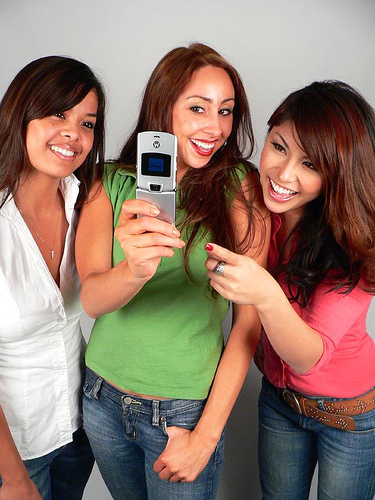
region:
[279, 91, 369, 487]
woman wearing blue jeans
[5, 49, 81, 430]
woman wearing white shirt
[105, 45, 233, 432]
woman holding a phone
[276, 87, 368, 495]
woman wearing brown belt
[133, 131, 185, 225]
silver motorola cell phone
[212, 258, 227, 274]
silver rings on her finger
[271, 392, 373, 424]
brown belt with a silver buckle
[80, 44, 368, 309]
two girls taking a selfie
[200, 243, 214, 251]
red fingernail polish on a fingernail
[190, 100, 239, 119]
brown eyes looking into phone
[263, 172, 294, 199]
pearly white teeth in mouth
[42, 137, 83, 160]
white teeth with red lipstick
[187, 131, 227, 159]
white teeth with red lipstick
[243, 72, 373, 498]
this is a lady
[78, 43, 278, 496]
this is a lady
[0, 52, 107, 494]
this is a lady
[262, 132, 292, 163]
an eye of a person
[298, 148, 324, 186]
an eye of a person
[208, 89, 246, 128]
an eye of a person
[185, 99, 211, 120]
an eye of a person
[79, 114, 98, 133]
an eye of a person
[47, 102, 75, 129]
an eye of a person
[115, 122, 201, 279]
this is a phone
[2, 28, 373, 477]
Three young females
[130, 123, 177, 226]
Outdated flip phone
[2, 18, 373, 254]
Three smiling girls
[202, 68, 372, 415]
A female in pink shirt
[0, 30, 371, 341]
Three best friends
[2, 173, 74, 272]
Beautiful white gold necklace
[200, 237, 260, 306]
Ring on the middle finger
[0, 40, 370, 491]
Three girls wearing jeans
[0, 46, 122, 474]
A girl in white shirt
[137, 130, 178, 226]
A silver flip phone.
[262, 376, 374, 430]
Brown belt on a woman's waist.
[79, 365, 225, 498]
Blue jeans with a thumb in the pocket.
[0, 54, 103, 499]
A smiling brown haired girl in white.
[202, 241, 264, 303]
Left hand of a woman in pink.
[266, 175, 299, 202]
An open mouth toothy smile of a pink shirt girl.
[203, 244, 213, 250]
Red fingernail of a girl.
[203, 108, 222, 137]
Long nose on a green shirt girl.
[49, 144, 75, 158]
White teeth of a girl in white.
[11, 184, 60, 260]
Silver necklace on a woman's neck.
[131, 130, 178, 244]
silver flip phone with blue and black panel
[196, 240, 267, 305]
woman pointing with finger in red nail polish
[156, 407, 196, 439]
thumb hooked into jean pocket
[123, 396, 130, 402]
button on blue jeans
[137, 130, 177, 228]
cell phone is silver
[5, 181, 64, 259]
necklace around neck is silver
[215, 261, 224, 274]
ring around finger is silver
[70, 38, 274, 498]
girl is wearing a green shirt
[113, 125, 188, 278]
right hand is holding a flip phone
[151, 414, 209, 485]
left hand with a thumb inside a pocket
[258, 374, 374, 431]
brown leather studded belt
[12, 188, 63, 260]
silver chain necklace with a pendant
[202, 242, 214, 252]
red painted finger nail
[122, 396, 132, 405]
round silver metal button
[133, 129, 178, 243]
silver flip phone is open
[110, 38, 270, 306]
girl has long dark hair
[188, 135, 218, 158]
bright smile with red lipstick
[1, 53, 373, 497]
three females standing together